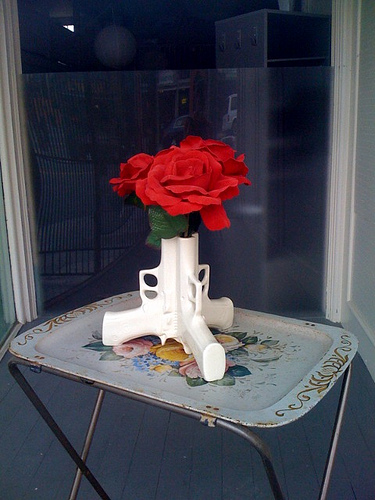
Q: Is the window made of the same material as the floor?
A: No, the window is made of glass and the floor is made of wood.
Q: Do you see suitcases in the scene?
A: No, there are no suitcases.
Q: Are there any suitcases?
A: No, there are no suitcases.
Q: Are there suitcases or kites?
A: No, there are no suitcases or kites.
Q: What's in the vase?
A: The flower is in the vase.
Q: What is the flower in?
A: The flower is in the vase.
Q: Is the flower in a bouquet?
A: No, the flower is in a vase.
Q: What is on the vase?
A: The flower is on the vase.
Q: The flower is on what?
A: The flower is on the vase.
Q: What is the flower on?
A: The flower is on the vase.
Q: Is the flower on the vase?
A: Yes, the flower is on the vase.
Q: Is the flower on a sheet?
A: No, the flower is on the vase.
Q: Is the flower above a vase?
A: Yes, the flower is above a vase.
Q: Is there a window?
A: Yes, there is a window.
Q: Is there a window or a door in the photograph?
A: Yes, there is a window.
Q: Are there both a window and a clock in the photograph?
A: No, there is a window but no clocks.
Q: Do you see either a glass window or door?
A: Yes, there is a glass window.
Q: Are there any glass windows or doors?
A: Yes, there is a glass window.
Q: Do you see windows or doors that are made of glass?
A: Yes, the window is made of glass.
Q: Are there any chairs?
A: No, there are no chairs.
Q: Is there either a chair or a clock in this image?
A: No, there are no chairs or clocks.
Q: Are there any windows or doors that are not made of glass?
A: No, there is a window but it is made of glass.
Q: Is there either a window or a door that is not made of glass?
A: No, there is a window but it is made of glass.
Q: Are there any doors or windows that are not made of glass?
A: No, there is a window but it is made of glass.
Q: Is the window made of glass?
A: Yes, the window is made of glass.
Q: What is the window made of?
A: The window is made of glass.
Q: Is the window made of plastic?
A: No, the window is made of glass.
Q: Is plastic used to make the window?
A: No, the window is made of glass.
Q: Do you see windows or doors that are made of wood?
A: No, there is a window but it is made of glass.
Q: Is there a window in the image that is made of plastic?
A: No, there is a window but it is made of glass.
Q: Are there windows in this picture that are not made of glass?
A: No, there is a window but it is made of glass.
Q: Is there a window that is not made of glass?
A: No, there is a window but it is made of glass.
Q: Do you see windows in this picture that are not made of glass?
A: No, there is a window but it is made of glass.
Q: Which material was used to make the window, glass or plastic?
A: The window is made of glass.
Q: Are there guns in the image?
A: Yes, there is a gun.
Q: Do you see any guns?
A: Yes, there is a gun.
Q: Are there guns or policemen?
A: Yes, there is a gun.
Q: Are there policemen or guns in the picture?
A: Yes, there is a gun.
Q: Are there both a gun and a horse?
A: No, there is a gun but no horses.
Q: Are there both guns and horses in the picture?
A: No, there is a gun but no horses.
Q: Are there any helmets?
A: No, there are no helmets.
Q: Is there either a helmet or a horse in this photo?
A: No, there are no helmets or horses.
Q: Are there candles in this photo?
A: No, there are no candles.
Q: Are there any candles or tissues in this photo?
A: No, there are no candles or tissues.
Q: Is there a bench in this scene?
A: No, there are no benches.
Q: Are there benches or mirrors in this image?
A: No, there are no benches or mirrors.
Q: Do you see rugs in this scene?
A: No, there are no rugs.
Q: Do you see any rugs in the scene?
A: No, there are no rugs.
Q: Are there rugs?
A: No, there are no rugs.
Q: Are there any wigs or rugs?
A: No, there are no rugs or wigs.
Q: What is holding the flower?
A: The vase is holding the flower.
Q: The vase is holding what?
A: The vase is holding the flower.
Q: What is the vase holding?
A: The vase is holding the flower.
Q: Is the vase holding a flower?
A: Yes, the vase is holding a flower.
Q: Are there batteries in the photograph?
A: No, there are no batteries.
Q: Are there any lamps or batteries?
A: No, there are no batteries or lamps.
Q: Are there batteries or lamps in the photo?
A: No, there are no batteries or lamps.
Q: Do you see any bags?
A: No, there are no bags.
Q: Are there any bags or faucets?
A: No, there are no bags or faucets.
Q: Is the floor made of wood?
A: Yes, the floor is made of wood.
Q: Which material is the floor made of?
A: The floor is made of wood.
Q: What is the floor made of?
A: The floor is made of wood.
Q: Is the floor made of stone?
A: No, the floor is made of wood.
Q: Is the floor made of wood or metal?
A: The floor is made of wood.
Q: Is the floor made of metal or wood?
A: The floor is made of wood.